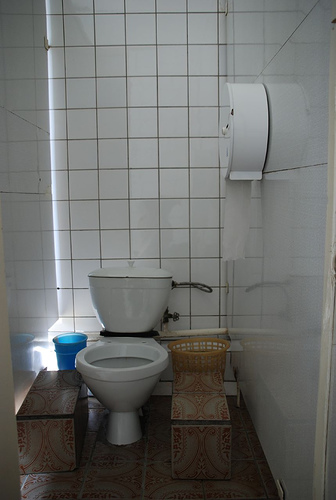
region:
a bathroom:
[2, 138, 331, 487]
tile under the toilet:
[101, 454, 148, 489]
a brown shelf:
[168, 376, 234, 469]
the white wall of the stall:
[10, 152, 59, 351]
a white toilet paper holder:
[216, 88, 275, 194]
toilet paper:
[221, 184, 243, 258]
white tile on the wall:
[62, 8, 227, 282]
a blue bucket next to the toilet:
[55, 331, 81, 368]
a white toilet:
[83, 269, 177, 444]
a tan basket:
[175, 340, 219, 370]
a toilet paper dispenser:
[219, 83, 267, 180]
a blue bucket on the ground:
[59, 330, 90, 376]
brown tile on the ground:
[149, 391, 238, 494]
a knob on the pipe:
[167, 310, 179, 323]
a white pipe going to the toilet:
[162, 326, 227, 334]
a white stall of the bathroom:
[240, 3, 333, 280]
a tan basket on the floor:
[174, 337, 223, 372]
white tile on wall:
[94, 13, 129, 50]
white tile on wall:
[154, 103, 194, 140]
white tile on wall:
[128, 136, 164, 168]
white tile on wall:
[65, 138, 105, 172]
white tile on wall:
[53, 194, 78, 232]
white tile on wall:
[93, 199, 137, 234]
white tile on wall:
[155, 195, 192, 237]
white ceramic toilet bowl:
[73, 264, 179, 450]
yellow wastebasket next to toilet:
[164, 329, 250, 382]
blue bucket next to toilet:
[49, 326, 91, 370]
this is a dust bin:
[162, 319, 234, 391]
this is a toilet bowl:
[74, 329, 166, 448]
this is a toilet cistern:
[72, 241, 199, 344]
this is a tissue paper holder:
[185, 65, 255, 267]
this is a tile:
[123, 194, 156, 228]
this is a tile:
[160, 195, 188, 228]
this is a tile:
[91, 166, 134, 198]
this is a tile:
[193, 263, 219, 290]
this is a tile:
[71, 200, 98, 229]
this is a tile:
[122, 139, 162, 165]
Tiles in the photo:
[128, 73, 183, 133]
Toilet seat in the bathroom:
[84, 332, 157, 431]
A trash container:
[172, 333, 226, 369]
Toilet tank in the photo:
[89, 259, 182, 324]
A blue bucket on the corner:
[51, 331, 88, 364]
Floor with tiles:
[111, 441, 158, 492]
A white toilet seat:
[72, 331, 167, 429]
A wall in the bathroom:
[121, 82, 191, 176]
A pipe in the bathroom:
[174, 275, 228, 298]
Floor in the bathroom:
[92, 469, 171, 494]